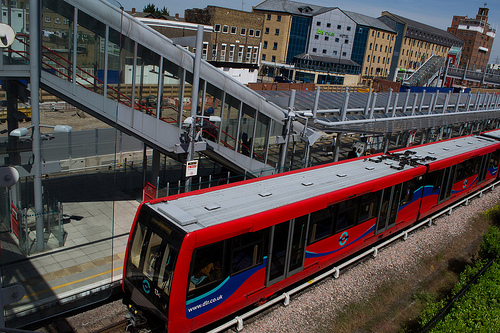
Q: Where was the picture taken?
A: It was taken at the station.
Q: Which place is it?
A: It is a station.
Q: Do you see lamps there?
A: Yes, there is a lamp.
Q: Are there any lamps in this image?
A: Yes, there is a lamp.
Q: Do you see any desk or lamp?
A: Yes, there is a lamp.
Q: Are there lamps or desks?
A: Yes, there is a lamp.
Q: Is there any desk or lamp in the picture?
A: Yes, there is a lamp.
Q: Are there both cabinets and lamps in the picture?
A: No, there is a lamp but no cabinets.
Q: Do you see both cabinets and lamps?
A: No, there is a lamp but no cabinets.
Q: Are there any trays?
A: No, there are no trays.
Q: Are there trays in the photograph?
A: No, there are no trays.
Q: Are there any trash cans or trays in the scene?
A: No, there are no trays or trash cans.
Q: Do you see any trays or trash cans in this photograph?
A: No, there are no trays or trash cans.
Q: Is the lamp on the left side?
A: Yes, the lamp is on the left of the image.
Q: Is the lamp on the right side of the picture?
A: No, the lamp is on the left of the image.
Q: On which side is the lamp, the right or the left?
A: The lamp is on the left of the image.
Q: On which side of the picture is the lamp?
A: The lamp is on the left of the image.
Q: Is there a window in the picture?
A: Yes, there is a window.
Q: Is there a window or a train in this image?
A: Yes, there is a window.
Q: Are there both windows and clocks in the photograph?
A: No, there is a window but no clocks.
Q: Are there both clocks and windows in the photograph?
A: No, there is a window but no clocks.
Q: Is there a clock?
A: No, there are no clocks.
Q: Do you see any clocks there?
A: No, there are no clocks.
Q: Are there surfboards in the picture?
A: No, there are no surfboards.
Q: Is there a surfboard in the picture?
A: No, there are no surfboards.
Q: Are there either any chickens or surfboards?
A: No, there are no surfboards or chickens.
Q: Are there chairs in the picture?
A: No, there are no chairs.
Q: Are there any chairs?
A: No, there are no chairs.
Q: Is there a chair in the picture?
A: No, there are no chairs.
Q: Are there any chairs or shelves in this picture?
A: No, there are no chairs or shelves.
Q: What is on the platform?
A: The wall is on the platform.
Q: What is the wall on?
A: The wall is on the platform.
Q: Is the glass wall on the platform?
A: Yes, the wall is on the platform.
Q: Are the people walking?
A: Yes, the people are walking.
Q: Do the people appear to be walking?
A: Yes, the people are walking.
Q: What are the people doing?
A: The people are walking.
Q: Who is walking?
A: The people are walking.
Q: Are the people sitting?
A: No, the people are walking.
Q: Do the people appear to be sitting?
A: No, the people are walking.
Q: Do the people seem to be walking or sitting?
A: The people are walking.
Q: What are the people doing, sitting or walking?
A: The people are walking.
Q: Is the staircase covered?
A: Yes, the staircase is covered.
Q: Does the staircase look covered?
A: Yes, the staircase is covered.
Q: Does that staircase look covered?
A: Yes, the staircase is covered.